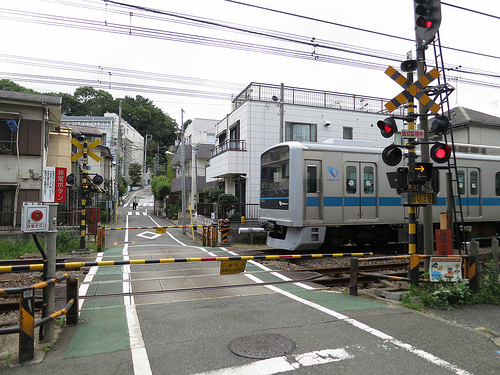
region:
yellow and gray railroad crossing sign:
[388, 62, 441, 104]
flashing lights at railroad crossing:
[379, 108, 470, 178]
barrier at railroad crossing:
[88, 245, 230, 290]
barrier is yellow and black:
[146, 250, 233, 272]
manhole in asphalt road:
[195, 283, 312, 369]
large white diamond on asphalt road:
[131, 225, 176, 250]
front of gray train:
[240, 136, 400, 238]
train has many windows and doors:
[261, 138, 483, 233]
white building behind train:
[255, 120, 282, 150]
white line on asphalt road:
[106, 294, 137, 373]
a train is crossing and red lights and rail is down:
[2, 73, 475, 343]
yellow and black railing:
[0, 280, 85, 332]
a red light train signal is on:
[381, 110, 459, 292]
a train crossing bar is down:
[0, 246, 372, 277]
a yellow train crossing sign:
[73, 134, 102, 165]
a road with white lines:
[27, 267, 497, 374]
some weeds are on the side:
[408, 262, 498, 304]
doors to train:
[296, 159, 376, 216]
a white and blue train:
[256, 144, 498, 246]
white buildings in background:
[3, 87, 383, 147]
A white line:
[322, 310, 366, 367]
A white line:
[330, 261, 384, 362]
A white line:
[362, 270, 397, 362]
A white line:
[357, 242, 431, 372]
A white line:
[335, 318, 359, 369]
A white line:
[348, 304, 396, 365]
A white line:
[345, 282, 377, 369]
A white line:
[358, 310, 389, 357]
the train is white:
[204, 103, 442, 309]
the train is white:
[257, 139, 497, 366]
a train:
[218, 107, 490, 224]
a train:
[168, 30, 455, 362]